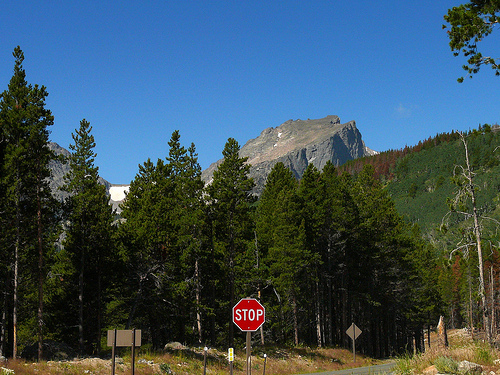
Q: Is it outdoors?
A: Yes, it is outdoors.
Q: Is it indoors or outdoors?
A: It is outdoors.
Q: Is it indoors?
A: No, it is outdoors.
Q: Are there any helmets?
A: No, there are no helmets.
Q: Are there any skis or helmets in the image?
A: No, there are no helmets or skis.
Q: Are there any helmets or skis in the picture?
A: No, there are no helmets or skis.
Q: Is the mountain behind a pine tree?
A: Yes, the mountain is behind a pine tree.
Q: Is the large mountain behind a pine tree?
A: Yes, the mountain is behind a pine tree.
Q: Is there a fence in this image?
A: No, there are no fences.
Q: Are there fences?
A: No, there are no fences.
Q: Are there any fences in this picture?
A: No, there are no fences.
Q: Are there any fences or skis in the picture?
A: No, there are no fences or skis.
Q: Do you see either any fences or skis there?
A: No, there are no fences or skis.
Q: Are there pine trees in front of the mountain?
A: Yes, there is a pine tree in front of the mountain.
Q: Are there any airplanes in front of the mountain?
A: No, there is a pine tree in front of the mountain.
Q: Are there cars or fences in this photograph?
A: No, there are no fences or cars.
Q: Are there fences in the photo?
A: No, there are no fences.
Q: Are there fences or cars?
A: No, there are no fences or cars.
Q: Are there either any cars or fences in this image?
A: No, there are no fences or cars.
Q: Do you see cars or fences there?
A: No, there are no fences or cars.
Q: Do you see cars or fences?
A: No, there are no fences or cars.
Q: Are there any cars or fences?
A: No, there are no fences or cars.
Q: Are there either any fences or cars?
A: No, there are no fences or cars.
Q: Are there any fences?
A: No, there are no fences.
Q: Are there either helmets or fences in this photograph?
A: No, there are no fences or helmets.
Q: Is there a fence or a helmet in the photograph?
A: No, there are no fences or helmets.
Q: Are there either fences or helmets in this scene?
A: No, there are no fences or helmets.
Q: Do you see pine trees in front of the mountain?
A: Yes, there is a pine tree in front of the mountain.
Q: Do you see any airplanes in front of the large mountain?
A: No, there is a pine tree in front of the mountain.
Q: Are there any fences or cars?
A: No, there are no fences or cars.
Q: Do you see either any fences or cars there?
A: No, there are no fences or cars.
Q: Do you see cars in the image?
A: No, there are no cars.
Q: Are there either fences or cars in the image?
A: No, there are no cars or fences.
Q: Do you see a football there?
A: No, there are no footballs.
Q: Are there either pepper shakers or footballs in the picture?
A: No, there are no footballs or pepper shakers.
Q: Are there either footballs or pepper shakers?
A: No, there are no footballs or pepper shakers.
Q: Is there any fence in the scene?
A: No, there are no fences.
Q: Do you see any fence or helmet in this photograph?
A: No, there are no fences or helmets.